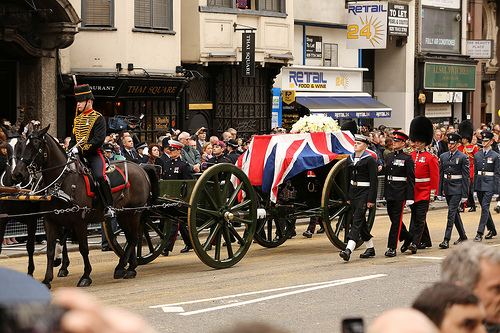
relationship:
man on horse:
[62, 86, 121, 223] [13, 118, 163, 294]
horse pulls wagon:
[13, 118, 163, 294] [161, 128, 380, 268]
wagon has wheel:
[161, 128, 380, 268] [321, 156, 378, 252]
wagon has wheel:
[161, 128, 380, 268] [187, 161, 260, 268]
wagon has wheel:
[161, 128, 380, 268] [103, 205, 174, 267]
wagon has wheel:
[161, 128, 380, 268] [247, 185, 297, 248]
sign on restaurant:
[68, 72, 191, 103] [61, 2, 189, 237]